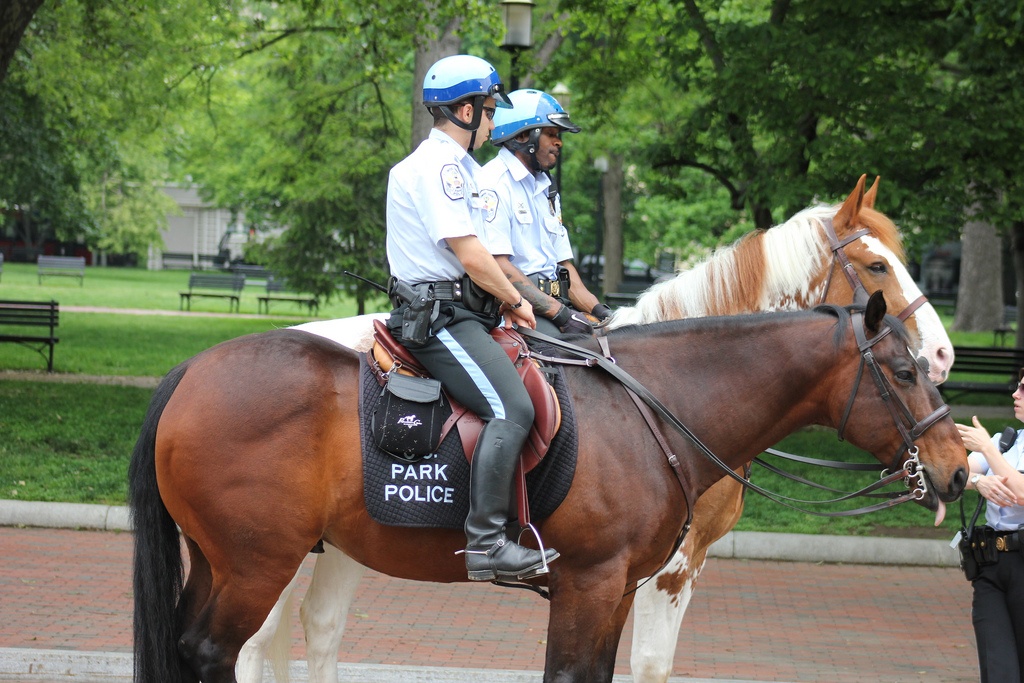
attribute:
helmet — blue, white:
[411, 40, 513, 111]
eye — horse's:
[861, 260, 885, 274]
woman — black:
[958, 375, 1019, 680]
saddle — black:
[356, 349, 573, 530]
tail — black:
[128, 355, 187, 672]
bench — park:
[169, 270, 240, 309]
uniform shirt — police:
[383, 130, 502, 288]